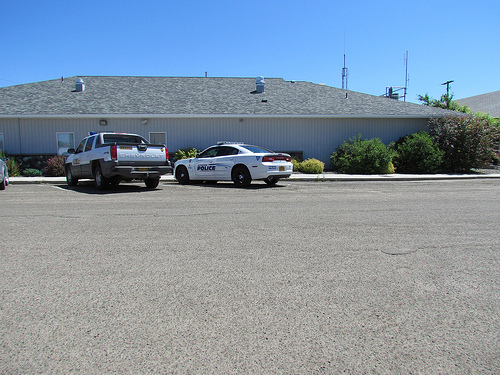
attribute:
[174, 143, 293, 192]
car — parked, whie, white, whtie, small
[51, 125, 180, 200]
truck — white, whie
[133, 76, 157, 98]
roof — gray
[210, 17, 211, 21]
sky — blue, clear, clera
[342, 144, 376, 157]
bushes — green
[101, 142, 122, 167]
lights — red, redy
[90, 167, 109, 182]
wheel — black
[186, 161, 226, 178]
logo — blue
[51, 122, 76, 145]
window — white